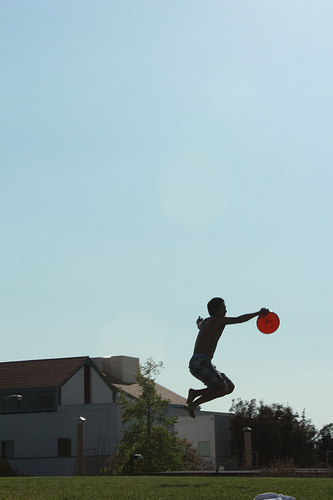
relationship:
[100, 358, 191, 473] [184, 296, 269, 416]
tree behind man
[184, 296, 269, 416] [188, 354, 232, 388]
man wearing shorts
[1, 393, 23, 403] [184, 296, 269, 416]
street light behind man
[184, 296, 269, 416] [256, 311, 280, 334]
man holding frisbee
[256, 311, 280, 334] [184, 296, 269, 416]
frisbee held by man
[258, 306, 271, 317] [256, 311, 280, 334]
hand holding frisbee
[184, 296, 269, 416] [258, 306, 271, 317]
man has a hand